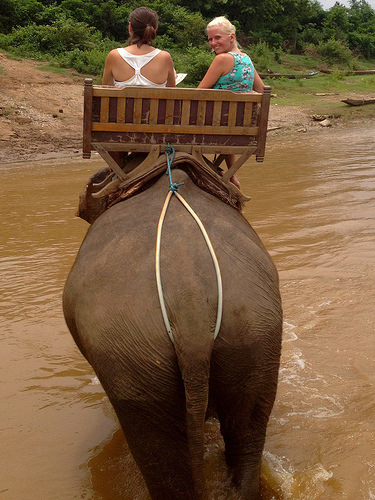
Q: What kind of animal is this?
A: Elephant.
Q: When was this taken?
A: Daytime.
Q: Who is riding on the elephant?
A: Women.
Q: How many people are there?
A: 2.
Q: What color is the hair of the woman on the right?
A: Blonde.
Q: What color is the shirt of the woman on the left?
A: White.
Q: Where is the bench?
A: On the elephant's back.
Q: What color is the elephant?
A: Gray.